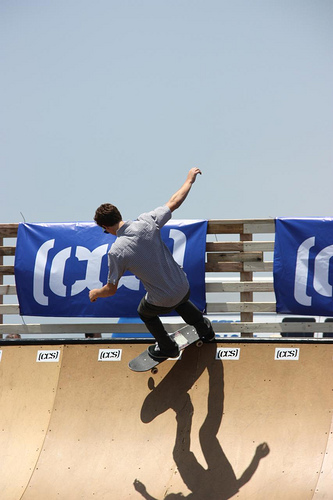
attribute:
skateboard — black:
[123, 313, 241, 374]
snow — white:
[253, 313, 284, 325]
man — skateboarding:
[63, 169, 225, 353]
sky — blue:
[17, 15, 311, 133]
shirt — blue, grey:
[106, 220, 201, 325]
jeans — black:
[129, 288, 205, 347]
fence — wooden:
[209, 215, 271, 326]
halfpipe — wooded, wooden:
[0, 330, 332, 498]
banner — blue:
[13, 217, 210, 314]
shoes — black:
[141, 333, 185, 360]